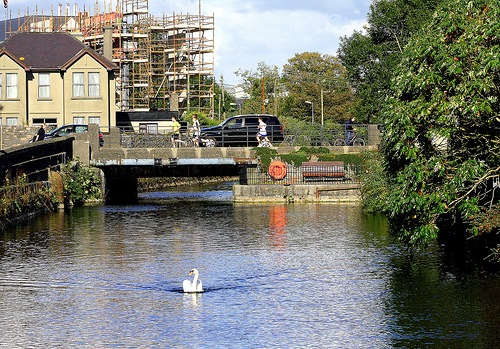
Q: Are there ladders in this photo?
A: No, there are no ladders.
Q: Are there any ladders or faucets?
A: No, there are no ladders or faucets.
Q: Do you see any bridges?
A: Yes, there is a bridge.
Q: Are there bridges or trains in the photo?
A: Yes, there is a bridge.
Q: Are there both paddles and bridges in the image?
A: No, there is a bridge but no paddles.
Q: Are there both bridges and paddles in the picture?
A: No, there is a bridge but no paddles.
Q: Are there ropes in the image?
A: No, there are no ropes.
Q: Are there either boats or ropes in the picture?
A: No, there are no ropes or boats.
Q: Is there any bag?
A: No, there are no bags.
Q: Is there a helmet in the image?
A: No, there are no helmets.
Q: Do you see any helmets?
A: No, there are no helmets.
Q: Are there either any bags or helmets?
A: No, there are no helmets or bags.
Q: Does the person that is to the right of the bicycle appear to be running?
A: Yes, the person is running.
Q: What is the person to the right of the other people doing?
A: The person is running.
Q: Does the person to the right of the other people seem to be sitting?
A: No, the person is running.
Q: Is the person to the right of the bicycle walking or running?
A: The person is running.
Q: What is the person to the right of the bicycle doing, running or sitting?
A: The person is running.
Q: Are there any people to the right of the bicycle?
A: Yes, there is a person to the right of the bicycle.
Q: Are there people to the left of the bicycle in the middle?
A: No, the person is to the right of the bicycle.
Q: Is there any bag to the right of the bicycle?
A: No, there is a person to the right of the bicycle.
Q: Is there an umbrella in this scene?
A: No, there are no umbrellas.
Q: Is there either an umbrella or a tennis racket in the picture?
A: No, there are no umbrellas or rackets.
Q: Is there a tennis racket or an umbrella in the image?
A: No, there are no umbrellas or rackets.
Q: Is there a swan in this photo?
A: Yes, there is a swan.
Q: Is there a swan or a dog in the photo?
A: Yes, there is a swan.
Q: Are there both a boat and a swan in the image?
A: No, there is a swan but no boats.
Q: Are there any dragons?
A: No, there are no dragons.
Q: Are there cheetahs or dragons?
A: No, there are no dragons or cheetahs.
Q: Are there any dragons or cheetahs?
A: No, there are no dragons or cheetahs.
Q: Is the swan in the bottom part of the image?
A: Yes, the swan is in the bottom of the image.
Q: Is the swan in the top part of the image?
A: No, the swan is in the bottom of the image.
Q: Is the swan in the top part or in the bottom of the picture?
A: The swan is in the bottom of the image.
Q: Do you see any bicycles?
A: Yes, there is a bicycle.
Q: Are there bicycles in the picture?
A: Yes, there is a bicycle.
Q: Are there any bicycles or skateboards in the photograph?
A: Yes, there is a bicycle.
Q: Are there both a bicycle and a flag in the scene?
A: No, there is a bicycle but no flags.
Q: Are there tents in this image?
A: No, there are no tents.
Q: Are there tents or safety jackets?
A: No, there are no tents or safety jackets.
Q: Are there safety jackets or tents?
A: No, there are no tents or safety jackets.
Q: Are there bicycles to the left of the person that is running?
A: Yes, there is a bicycle to the left of the person.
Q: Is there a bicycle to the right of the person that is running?
A: No, the bicycle is to the left of the person.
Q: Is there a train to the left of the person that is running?
A: No, there is a bicycle to the left of the person.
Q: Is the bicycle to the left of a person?
A: Yes, the bicycle is to the left of a person.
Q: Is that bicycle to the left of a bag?
A: No, the bicycle is to the left of a person.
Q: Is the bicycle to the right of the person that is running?
A: No, the bicycle is to the left of the person.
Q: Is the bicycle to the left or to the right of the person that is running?
A: The bicycle is to the left of the person.